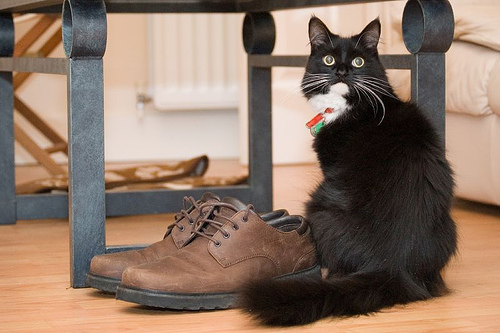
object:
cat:
[239, 16, 459, 327]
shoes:
[115, 196, 313, 308]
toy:
[304, 93, 345, 134]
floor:
[1, 166, 498, 331]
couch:
[382, 3, 500, 209]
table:
[1, 0, 454, 288]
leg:
[60, 1, 109, 285]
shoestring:
[192, 199, 236, 242]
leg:
[243, 11, 275, 209]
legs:
[1, 3, 20, 227]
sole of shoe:
[116, 289, 245, 313]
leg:
[402, 0, 453, 166]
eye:
[323, 54, 335, 66]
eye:
[352, 56, 365, 68]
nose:
[336, 69, 347, 77]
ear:
[307, 17, 332, 44]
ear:
[359, 17, 382, 49]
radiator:
[147, 15, 239, 109]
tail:
[241, 272, 453, 326]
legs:
[12, 126, 66, 179]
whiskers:
[379, 113, 386, 126]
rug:
[18, 153, 246, 191]